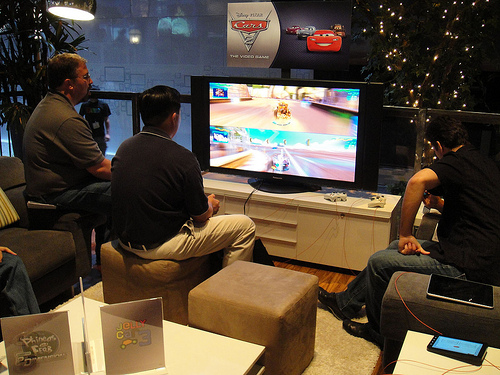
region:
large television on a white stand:
[181, 70, 417, 286]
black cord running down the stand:
[237, 176, 260, 216]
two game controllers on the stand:
[321, 188, 389, 210]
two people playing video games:
[23, 37, 395, 290]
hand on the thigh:
[394, 230, 427, 262]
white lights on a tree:
[351, 0, 498, 147]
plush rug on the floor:
[274, 293, 391, 373]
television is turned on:
[187, 69, 381, 201]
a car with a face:
[304, 25, 346, 54]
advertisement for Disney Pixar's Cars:
[223, 1, 365, 73]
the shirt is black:
[108, 122, 193, 243]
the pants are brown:
[188, 215, 259, 255]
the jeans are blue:
[3, 259, 48, 316]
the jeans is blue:
[358, 229, 439, 296]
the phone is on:
[420, 332, 493, 363]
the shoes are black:
[336, 318, 386, 345]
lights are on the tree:
[359, 20, 496, 110]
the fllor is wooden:
[297, 261, 359, 283]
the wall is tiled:
[113, 23, 230, 73]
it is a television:
[185, 70, 382, 192]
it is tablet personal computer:
[414, 269, 497, 364]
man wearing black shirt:
[99, 125, 213, 247]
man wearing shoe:
[317, 276, 382, 356]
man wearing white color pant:
[102, 212, 264, 274]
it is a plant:
[384, 0, 498, 97]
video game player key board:
[324, 187, 392, 213]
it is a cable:
[391, 274, 426, 339]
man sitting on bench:
[88, 69, 280, 284]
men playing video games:
[27, 42, 386, 282]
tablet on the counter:
[412, 324, 488, 373]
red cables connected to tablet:
[389, 297, 492, 372]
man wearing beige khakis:
[126, 197, 271, 269]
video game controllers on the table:
[308, 176, 383, 213]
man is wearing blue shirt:
[90, 127, 245, 261]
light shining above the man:
[34, 2, 114, 32]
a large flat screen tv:
[180, 66, 384, 206]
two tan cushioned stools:
[76, 217, 342, 364]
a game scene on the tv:
[211, 89, 364, 189]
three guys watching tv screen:
[25, 47, 490, 293]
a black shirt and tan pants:
[100, 125, 271, 274]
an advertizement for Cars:
[220, 5, 364, 73]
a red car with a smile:
[296, 17, 353, 60]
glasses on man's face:
[62, 61, 116, 92]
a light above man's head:
[43, 2, 108, 43]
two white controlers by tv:
[303, 179, 394, 235]